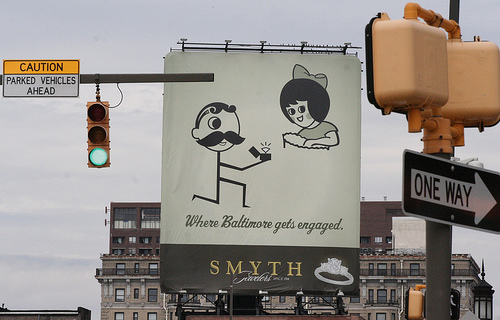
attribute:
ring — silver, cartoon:
[257, 142, 274, 154]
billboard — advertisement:
[158, 39, 362, 287]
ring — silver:
[313, 256, 354, 287]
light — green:
[87, 148, 111, 167]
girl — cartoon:
[279, 61, 341, 155]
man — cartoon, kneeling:
[189, 101, 274, 213]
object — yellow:
[363, 3, 498, 155]